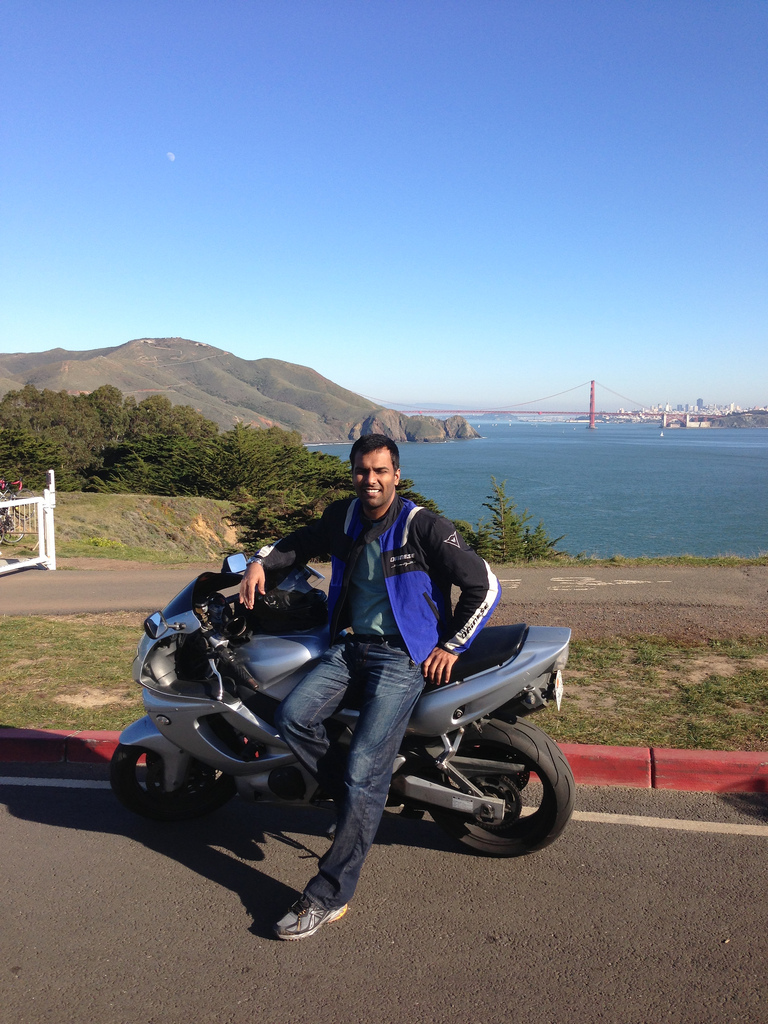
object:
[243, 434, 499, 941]
man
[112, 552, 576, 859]
bike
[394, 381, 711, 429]
bridge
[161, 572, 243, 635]
windshield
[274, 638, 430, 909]
jeans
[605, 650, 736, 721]
grass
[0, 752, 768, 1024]
road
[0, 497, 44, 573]
fence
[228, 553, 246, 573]
rearview mirrors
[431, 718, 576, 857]
wheel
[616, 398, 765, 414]
san francisco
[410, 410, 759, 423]
horizon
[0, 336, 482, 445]
hills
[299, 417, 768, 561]
bay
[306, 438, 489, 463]
strait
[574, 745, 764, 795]
curb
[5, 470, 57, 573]
gate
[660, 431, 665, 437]
boat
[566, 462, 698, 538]
water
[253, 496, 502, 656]
jacket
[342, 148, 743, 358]
sunlight